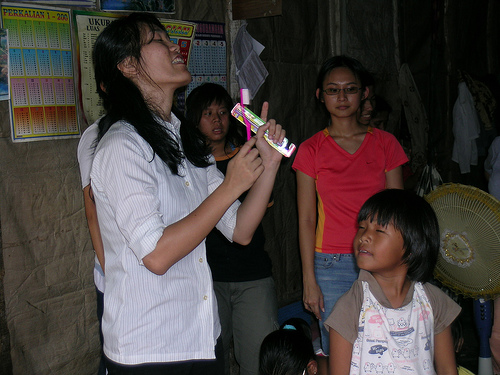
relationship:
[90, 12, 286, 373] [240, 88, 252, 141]
lady holding toothbrush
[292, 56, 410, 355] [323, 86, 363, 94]
woman wearing glasses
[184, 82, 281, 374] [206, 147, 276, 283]
lady wearing shirt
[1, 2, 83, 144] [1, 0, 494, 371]
calendar on wall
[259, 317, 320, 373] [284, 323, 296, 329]
lady wearing hair tie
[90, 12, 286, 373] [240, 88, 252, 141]
woman has toothbrush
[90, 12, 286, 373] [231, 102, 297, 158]
woman has toothbrush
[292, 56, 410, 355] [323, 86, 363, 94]
woman has glasses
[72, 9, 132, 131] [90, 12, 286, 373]
sign behind lady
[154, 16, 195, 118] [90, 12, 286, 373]
sign behind lady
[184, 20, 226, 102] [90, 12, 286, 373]
sign behind lady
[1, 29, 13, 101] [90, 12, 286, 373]
sign behind lady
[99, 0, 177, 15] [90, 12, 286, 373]
sign behind lady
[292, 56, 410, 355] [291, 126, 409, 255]
woman wearing shirt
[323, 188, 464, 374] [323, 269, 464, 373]
child wearing t-shirt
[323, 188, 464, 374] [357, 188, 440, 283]
child has hair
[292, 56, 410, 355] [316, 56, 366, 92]
woman has hair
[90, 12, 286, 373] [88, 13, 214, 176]
woman has hair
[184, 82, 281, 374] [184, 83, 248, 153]
woman has hair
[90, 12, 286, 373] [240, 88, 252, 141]
woman holding toothbrush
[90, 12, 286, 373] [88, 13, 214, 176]
lady has hair